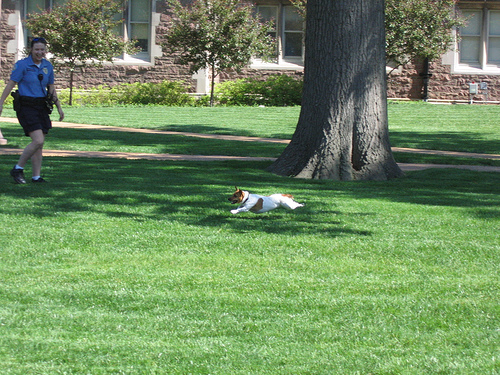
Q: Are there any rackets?
A: No, there are no rackets.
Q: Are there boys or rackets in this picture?
A: No, there are no rackets or boys.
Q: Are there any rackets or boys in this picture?
A: No, there are no rackets or boys.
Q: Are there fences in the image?
A: No, there are no fences.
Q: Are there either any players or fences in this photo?
A: No, there are no fences or players.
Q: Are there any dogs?
A: Yes, there is a dog.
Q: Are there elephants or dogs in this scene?
A: Yes, there is a dog.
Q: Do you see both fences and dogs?
A: No, there is a dog but no fences.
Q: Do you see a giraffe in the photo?
A: No, there are no giraffes.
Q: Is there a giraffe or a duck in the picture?
A: No, there are no giraffes or ducks.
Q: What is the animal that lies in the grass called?
A: The animal is a dog.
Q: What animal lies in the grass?
A: The animal is a dog.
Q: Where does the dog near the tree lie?
A: The dog lies in the grass.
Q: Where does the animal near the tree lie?
A: The dog lies in the grass.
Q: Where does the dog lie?
A: The dog lies in the grass.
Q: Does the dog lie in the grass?
A: Yes, the dog lies in the grass.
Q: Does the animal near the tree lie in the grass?
A: Yes, the dog lies in the grass.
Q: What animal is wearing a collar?
A: The dog is wearing a collar.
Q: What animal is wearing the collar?
A: The dog is wearing a collar.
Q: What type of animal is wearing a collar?
A: The animal is a dog.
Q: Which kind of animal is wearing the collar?
A: The animal is a dog.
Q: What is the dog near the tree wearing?
A: The dog is wearing a collar.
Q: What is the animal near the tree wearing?
A: The dog is wearing a collar.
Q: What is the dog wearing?
A: The dog is wearing a collar.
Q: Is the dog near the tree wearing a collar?
A: Yes, the dog is wearing a collar.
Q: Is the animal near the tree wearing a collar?
A: Yes, the dog is wearing a collar.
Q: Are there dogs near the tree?
A: Yes, there is a dog near the tree.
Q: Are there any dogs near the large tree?
A: Yes, there is a dog near the tree.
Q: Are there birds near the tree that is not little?
A: No, there is a dog near the tree.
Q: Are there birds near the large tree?
A: No, there is a dog near the tree.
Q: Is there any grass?
A: Yes, there is grass.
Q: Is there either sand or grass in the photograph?
A: Yes, there is grass.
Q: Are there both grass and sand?
A: No, there is grass but no sand.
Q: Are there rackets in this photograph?
A: No, there are no rackets.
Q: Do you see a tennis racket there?
A: No, there are no rackets.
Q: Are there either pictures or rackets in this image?
A: No, there are no rackets or pictures.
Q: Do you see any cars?
A: No, there are no cars.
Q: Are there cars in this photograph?
A: No, there are no cars.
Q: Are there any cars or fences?
A: No, there are no cars or fences.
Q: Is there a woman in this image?
A: Yes, there is a woman.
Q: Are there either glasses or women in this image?
A: Yes, there is a woman.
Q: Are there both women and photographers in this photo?
A: No, there is a woman but no photographers.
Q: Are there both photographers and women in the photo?
A: No, there is a woman but no photographers.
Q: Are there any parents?
A: No, there are no parents.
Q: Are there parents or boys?
A: No, there are no parents or boys.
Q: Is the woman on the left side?
A: Yes, the woman is on the left of the image.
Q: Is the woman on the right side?
A: No, the woman is on the left of the image.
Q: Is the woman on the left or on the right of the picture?
A: The woman is on the left of the image.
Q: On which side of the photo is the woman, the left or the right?
A: The woman is on the left of the image.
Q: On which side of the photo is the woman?
A: The woman is on the left of the image.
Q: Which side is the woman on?
A: The woman is on the left of the image.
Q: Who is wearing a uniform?
A: The woman is wearing a uniform.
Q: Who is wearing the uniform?
A: The woman is wearing a uniform.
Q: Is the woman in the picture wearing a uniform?
A: Yes, the woman is wearing a uniform.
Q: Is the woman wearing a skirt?
A: No, the woman is wearing a uniform.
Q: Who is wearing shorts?
A: The woman is wearing shorts.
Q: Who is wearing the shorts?
A: The woman is wearing shorts.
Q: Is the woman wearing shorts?
A: Yes, the woman is wearing shorts.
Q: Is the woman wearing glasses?
A: No, the woman is wearing shorts.